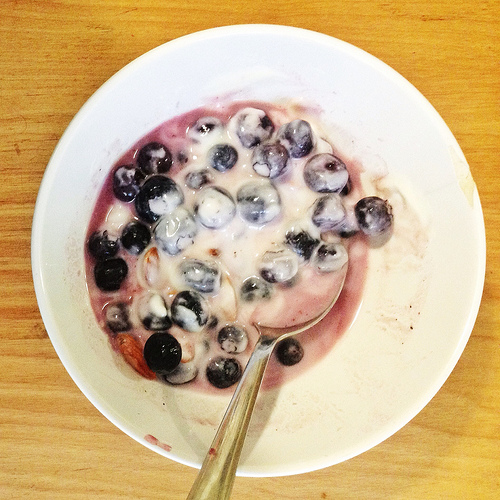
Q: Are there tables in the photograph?
A: Yes, there is a table.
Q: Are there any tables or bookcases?
A: Yes, there is a table.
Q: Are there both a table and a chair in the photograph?
A: No, there is a table but no chairs.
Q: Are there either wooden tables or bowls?
A: Yes, there is a wood table.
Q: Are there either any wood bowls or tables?
A: Yes, there is a wood table.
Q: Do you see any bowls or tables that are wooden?
A: Yes, the table is wooden.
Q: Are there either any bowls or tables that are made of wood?
A: Yes, the table is made of wood.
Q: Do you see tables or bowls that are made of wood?
A: Yes, the table is made of wood.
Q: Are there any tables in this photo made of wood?
A: Yes, there is a table that is made of wood.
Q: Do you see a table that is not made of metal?
A: Yes, there is a table that is made of wood.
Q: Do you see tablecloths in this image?
A: No, there are no tablecloths.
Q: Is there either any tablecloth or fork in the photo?
A: No, there are no tablecloths or forks.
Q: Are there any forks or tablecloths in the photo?
A: No, there are no tablecloths or forks.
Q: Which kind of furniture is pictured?
A: The furniture is a table.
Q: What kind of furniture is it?
A: The piece of furniture is a table.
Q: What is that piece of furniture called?
A: This is a table.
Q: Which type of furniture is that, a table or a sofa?
A: This is a table.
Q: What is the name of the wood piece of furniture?
A: The piece of furniture is a table.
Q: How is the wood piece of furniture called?
A: The piece of furniture is a table.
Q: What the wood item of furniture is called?
A: The piece of furniture is a table.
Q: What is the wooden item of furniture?
A: The piece of furniture is a table.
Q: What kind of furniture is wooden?
A: The furniture is a table.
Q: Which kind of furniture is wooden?
A: The furniture is a table.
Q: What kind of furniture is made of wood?
A: The furniture is a table.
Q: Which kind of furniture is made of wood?
A: The furniture is a table.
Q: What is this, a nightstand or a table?
A: This is a table.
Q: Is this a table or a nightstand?
A: This is a table.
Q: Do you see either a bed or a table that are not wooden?
A: No, there is a table but it is wooden.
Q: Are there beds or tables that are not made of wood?
A: No, there is a table but it is made of wood.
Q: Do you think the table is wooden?
A: Yes, the table is wooden.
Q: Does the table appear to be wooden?
A: Yes, the table is wooden.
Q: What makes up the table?
A: The table is made of wood.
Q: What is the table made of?
A: The table is made of wood.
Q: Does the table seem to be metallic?
A: No, the table is wooden.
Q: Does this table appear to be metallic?
A: No, the table is wooden.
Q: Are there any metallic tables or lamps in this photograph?
A: No, there is a table but it is wooden.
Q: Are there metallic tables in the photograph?
A: No, there is a table but it is wooden.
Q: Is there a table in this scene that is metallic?
A: No, there is a table but it is wooden.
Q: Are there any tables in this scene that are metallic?
A: No, there is a table but it is wooden.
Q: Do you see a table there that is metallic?
A: No, there is a table but it is wooden.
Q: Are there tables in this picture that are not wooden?
A: No, there is a table but it is wooden.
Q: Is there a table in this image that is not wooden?
A: No, there is a table but it is wooden.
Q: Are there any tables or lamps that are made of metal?
A: No, there is a table but it is made of wood.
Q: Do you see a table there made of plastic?
A: No, there is a table but it is made of wood.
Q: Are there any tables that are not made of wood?
A: No, there is a table but it is made of wood.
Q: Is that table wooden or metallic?
A: The table is wooden.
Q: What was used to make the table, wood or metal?
A: The table is made of wood.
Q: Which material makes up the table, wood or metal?
A: The table is made of wood.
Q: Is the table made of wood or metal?
A: The table is made of wood.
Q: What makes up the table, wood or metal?
A: The table is made of wood.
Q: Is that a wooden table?
A: Yes, that is a wooden table.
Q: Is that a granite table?
A: No, that is a wooden table.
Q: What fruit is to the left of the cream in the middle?
A: The fruit is a berry.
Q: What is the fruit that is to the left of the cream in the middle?
A: The fruit is a berry.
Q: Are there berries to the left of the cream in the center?
A: Yes, there is a berry to the left of the cream.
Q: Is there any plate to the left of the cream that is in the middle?
A: No, there is a berry to the left of the cream.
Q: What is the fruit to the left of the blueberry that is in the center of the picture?
A: The fruit is a berry.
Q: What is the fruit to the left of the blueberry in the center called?
A: The fruit is a berry.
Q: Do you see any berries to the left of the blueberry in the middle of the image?
A: Yes, there is a berry to the left of the blueberry.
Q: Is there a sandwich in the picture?
A: No, there are no sandwiches.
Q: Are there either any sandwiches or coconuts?
A: No, there are no sandwiches or coconuts.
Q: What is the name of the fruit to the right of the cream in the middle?
A: The fruit is a blueberry.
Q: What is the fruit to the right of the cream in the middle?
A: The fruit is a blueberry.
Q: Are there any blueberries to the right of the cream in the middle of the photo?
A: Yes, there is a blueberry to the right of the cream.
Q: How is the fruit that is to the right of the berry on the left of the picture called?
A: The fruit is a blueberry.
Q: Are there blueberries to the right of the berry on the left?
A: Yes, there is a blueberry to the right of the berry.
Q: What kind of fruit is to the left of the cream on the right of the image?
A: The fruit is a blueberry.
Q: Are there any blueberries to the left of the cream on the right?
A: Yes, there is a blueberry to the left of the cream.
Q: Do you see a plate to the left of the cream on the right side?
A: No, there is a blueberry to the left of the cream.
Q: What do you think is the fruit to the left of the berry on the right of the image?
A: The fruit is a blueberry.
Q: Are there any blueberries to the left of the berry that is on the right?
A: Yes, there is a blueberry to the left of the berry.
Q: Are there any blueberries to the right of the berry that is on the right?
A: No, the blueberry is to the left of the berry.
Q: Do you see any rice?
A: No, there is no rice.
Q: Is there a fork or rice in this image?
A: No, there are no rice or forks.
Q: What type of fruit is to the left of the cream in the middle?
A: The fruit is a blueberry.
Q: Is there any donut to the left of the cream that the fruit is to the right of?
A: No, there is a blueberry to the left of the cream.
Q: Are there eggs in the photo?
A: No, there are no eggs.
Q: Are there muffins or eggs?
A: No, there are no eggs or muffins.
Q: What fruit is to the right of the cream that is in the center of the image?
A: The fruit is a blueberry.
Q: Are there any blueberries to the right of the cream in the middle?
A: Yes, there is a blueberry to the right of the cream.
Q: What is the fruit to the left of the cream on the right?
A: The fruit is a blueberry.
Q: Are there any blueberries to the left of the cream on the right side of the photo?
A: Yes, there is a blueberry to the left of the cream.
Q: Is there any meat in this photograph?
A: No, there is no meat.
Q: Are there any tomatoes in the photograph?
A: No, there are no tomatoes.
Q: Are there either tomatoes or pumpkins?
A: No, there are no tomatoes or pumpkins.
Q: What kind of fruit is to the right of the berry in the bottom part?
A: The fruit is a blueberry.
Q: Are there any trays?
A: No, there are no trays.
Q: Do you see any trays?
A: No, there are no trays.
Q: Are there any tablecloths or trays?
A: No, there are no trays or tablecloths.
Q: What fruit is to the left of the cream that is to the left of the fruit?
A: The fruit is a blueberry.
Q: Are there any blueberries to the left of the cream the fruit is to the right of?
A: Yes, there is a blueberry to the left of the cream.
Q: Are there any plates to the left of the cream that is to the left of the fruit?
A: No, there is a blueberry to the left of the cream.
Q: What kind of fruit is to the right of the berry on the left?
A: The fruit is a blueberry.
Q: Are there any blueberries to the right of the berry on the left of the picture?
A: Yes, there is a blueberry to the right of the berry.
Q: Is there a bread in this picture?
A: No, there is no breads.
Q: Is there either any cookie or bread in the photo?
A: No, there are no breads or cookies.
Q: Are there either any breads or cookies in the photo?
A: No, there are no breads or cookies.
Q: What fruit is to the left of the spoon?
A: The fruit is a berry.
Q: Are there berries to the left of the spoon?
A: Yes, there is a berry to the left of the spoon.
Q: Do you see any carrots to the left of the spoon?
A: No, there is a berry to the left of the spoon.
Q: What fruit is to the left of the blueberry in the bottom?
A: The fruit is a berry.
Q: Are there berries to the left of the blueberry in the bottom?
A: Yes, there is a berry to the left of the blueberry.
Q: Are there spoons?
A: Yes, there is a spoon.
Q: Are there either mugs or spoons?
A: Yes, there is a spoon.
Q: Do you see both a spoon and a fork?
A: No, there is a spoon but no forks.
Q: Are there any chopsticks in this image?
A: No, there are no chopsticks.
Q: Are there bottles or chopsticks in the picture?
A: No, there are no chopsticks or bottles.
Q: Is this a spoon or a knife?
A: This is a spoon.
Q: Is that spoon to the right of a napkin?
A: No, the spoon is to the right of the berry.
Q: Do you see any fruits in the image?
A: Yes, there is a fruit.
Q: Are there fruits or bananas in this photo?
A: Yes, there is a fruit.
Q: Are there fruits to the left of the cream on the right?
A: Yes, there is a fruit to the left of the cream.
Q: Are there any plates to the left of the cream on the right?
A: No, there is a fruit to the left of the cream.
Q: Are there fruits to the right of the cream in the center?
A: Yes, there is a fruit to the right of the cream.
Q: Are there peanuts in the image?
A: No, there are no peanuts.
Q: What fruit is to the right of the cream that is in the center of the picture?
A: The fruit is a berry.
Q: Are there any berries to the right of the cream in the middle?
A: Yes, there is a berry to the right of the cream.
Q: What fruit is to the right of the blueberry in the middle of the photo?
A: The fruit is a berry.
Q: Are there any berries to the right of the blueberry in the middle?
A: Yes, there is a berry to the right of the blueberry.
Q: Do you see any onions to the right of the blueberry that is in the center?
A: No, there is a berry to the right of the blueberry.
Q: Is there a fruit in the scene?
A: Yes, there is a fruit.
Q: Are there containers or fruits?
A: Yes, there is a fruit.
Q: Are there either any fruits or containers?
A: Yes, there is a fruit.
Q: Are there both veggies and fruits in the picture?
A: No, there is a fruit but no vegetables.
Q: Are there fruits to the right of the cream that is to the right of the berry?
A: Yes, there is a fruit to the right of the cream.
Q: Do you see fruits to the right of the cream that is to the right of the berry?
A: Yes, there is a fruit to the right of the cream.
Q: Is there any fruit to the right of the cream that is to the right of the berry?
A: Yes, there is a fruit to the right of the cream.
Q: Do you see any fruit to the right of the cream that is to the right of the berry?
A: Yes, there is a fruit to the right of the cream.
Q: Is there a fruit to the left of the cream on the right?
A: Yes, there is a fruit to the left of the cream.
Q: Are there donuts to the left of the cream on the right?
A: No, there is a fruit to the left of the cream.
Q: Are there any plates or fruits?
A: Yes, there is a fruit.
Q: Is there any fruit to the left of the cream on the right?
A: Yes, there is a fruit to the left of the cream.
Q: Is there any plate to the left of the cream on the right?
A: No, there is a fruit to the left of the cream.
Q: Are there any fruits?
A: Yes, there is a fruit.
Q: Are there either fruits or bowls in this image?
A: Yes, there is a fruit.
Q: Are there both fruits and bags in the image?
A: No, there is a fruit but no bags.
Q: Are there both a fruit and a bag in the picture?
A: No, there is a fruit but no bags.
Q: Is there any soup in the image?
A: No, there is no soup.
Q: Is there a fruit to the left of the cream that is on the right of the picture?
A: Yes, there is a fruit to the left of the cream.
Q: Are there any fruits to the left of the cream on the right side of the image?
A: Yes, there is a fruit to the left of the cream.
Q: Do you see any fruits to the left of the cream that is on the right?
A: Yes, there is a fruit to the left of the cream.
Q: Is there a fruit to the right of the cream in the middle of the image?
A: Yes, there is a fruit to the right of the cream.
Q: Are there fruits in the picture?
A: Yes, there is a fruit.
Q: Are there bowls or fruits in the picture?
A: Yes, there is a fruit.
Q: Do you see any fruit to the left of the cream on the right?
A: Yes, there is a fruit to the left of the cream.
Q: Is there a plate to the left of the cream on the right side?
A: No, there is a fruit to the left of the cream.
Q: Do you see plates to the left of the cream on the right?
A: No, there is a fruit to the left of the cream.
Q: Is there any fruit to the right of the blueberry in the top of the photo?
A: Yes, there is a fruit to the right of the blueberry.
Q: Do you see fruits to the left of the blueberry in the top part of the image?
A: No, the fruit is to the right of the blueberry.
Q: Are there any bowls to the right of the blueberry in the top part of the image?
A: No, there is a fruit to the right of the blueberry.